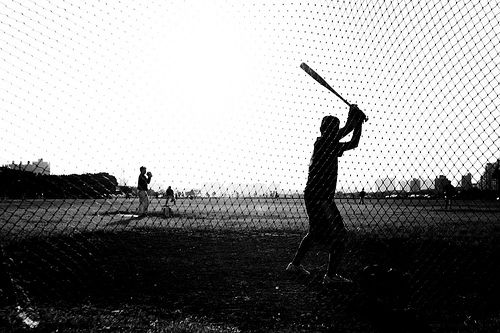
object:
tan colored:
[305, 189, 336, 240]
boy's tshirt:
[298, 132, 345, 201]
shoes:
[284, 258, 313, 279]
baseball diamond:
[0, 195, 500, 332]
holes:
[178, 213, 190, 225]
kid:
[282, 103, 369, 289]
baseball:
[146, 170, 155, 180]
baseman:
[440, 183, 456, 213]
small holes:
[172, 228, 185, 242]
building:
[2, 157, 53, 179]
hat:
[318, 115, 344, 131]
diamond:
[117, 209, 141, 219]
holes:
[213, 210, 224, 224]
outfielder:
[161, 184, 183, 208]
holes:
[212, 189, 225, 203]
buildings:
[477, 157, 500, 193]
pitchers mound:
[93, 208, 198, 221]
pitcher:
[133, 165, 154, 217]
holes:
[115, 179, 131, 193]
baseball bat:
[297, 58, 372, 122]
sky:
[0, 1, 500, 197]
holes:
[238, 203, 252, 220]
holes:
[23, 160, 38, 174]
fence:
[0, 0, 500, 332]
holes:
[480, 209, 496, 222]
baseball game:
[274, 62, 377, 289]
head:
[317, 114, 345, 139]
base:
[131, 210, 165, 222]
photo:
[0, 0, 500, 332]